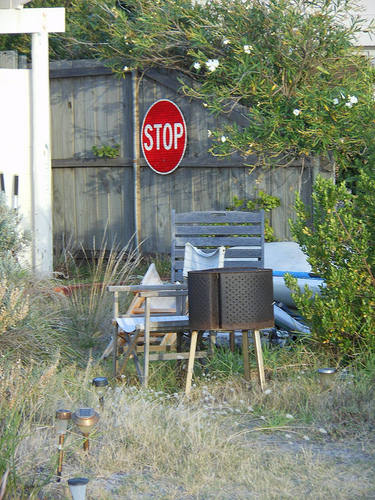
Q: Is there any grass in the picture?
A: Yes, there is grass.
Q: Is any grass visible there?
A: Yes, there is grass.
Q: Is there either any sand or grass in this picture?
A: Yes, there is grass.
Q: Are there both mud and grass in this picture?
A: No, there is grass but no mud.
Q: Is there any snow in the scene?
A: No, there is no snow.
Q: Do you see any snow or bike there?
A: No, there are no snow or bikes.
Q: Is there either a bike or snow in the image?
A: No, there are no snow or bikes.